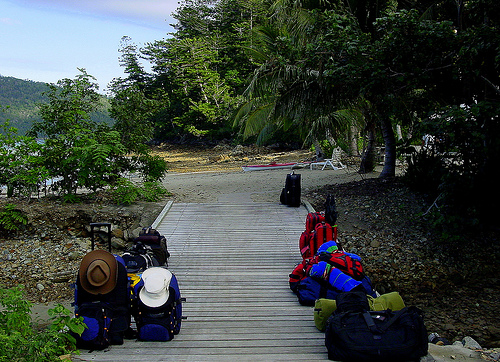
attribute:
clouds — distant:
[95, 2, 179, 26]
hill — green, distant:
[0, 74, 117, 137]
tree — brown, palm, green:
[244, 1, 499, 184]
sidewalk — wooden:
[58, 198, 396, 361]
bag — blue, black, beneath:
[130, 268, 182, 343]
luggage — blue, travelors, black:
[289, 239, 373, 305]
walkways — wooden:
[72, 197, 382, 361]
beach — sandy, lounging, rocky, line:
[149, 166, 386, 201]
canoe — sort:
[245, 159, 297, 175]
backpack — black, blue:
[72, 257, 131, 353]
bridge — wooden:
[88, 204, 346, 361]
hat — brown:
[77, 249, 121, 298]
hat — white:
[139, 265, 174, 308]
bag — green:
[315, 289, 413, 329]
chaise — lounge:
[305, 147, 350, 173]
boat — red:
[241, 161, 299, 175]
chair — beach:
[310, 147, 350, 171]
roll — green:
[312, 290, 407, 330]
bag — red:
[302, 212, 340, 258]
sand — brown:
[183, 184, 219, 199]